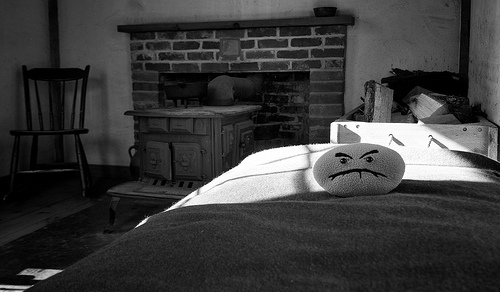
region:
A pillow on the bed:
[315, 145, 405, 192]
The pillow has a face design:
[314, 135, 401, 189]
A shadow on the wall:
[68, 64, 120, 159]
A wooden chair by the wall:
[14, 60, 94, 185]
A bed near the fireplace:
[26, 146, 497, 287]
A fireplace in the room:
[163, 73, 308, 153]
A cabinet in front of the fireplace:
[129, 101, 256, 177]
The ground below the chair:
[1, 163, 126, 240]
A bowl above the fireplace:
[313, 2, 341, 17]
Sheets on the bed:
[50, 145, 498, 289]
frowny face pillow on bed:
[297, 135, 414, 192]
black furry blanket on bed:
[68, 190, 410, 290]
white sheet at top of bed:
[246, 135, 306, 166]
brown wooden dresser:
[107, 97, 242, 177]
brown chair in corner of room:
[6, 50, 99, 206]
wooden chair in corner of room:
[1, 55, 96, 231]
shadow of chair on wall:
[79, 52, 127, 164]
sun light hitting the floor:
[15, 255, 57, 290]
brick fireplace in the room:
[108, 15, 362, 92]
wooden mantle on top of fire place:
[122, 6, 350, 38]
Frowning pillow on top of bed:
[309, 141, 407, 198]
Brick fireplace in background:
[120, 20, 343, 157]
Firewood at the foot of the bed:
[333, 66, 498, 148]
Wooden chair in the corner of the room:
[17, 60, 97, 200]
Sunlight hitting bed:
[178, 144, 482, 196]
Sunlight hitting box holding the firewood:
[331, 117, 498, 156]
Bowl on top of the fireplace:
[309, 3, 341, 18]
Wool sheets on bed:
[25, 141, 499, 290]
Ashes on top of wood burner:
[127, 99, 264, 119]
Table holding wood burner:
[99, 175, 193, 222]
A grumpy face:
[331, 147, 390, 184]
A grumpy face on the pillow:
[317, 147, 402, 199]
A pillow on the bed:
[150, 137, 493, 290]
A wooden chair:
[14, 59, 111, 200]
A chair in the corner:
[9, 59, 110, 199]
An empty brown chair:
[6, 59, 106, 201]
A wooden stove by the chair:
[0, 57, 256, 187]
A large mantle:
[108, 11, 364, 34]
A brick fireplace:
[132, 27, 342, 150]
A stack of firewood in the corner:
[358, 82, 470, 125]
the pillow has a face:
[318, 143, 398, 195]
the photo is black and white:
[0, 0, 496, 288]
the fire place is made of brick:
[123, 10, 353, 168]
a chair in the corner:
[11, 66, 101, 208]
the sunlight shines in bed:
[170, 143, 499, 210]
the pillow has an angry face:
[308, 144, 401, 193]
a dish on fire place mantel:
[311, 2, 343, 16]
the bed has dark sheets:
[26, 149, 498, 289]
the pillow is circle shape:
[308, 145, 404, 195]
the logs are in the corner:
[351, 69, 471, 124]